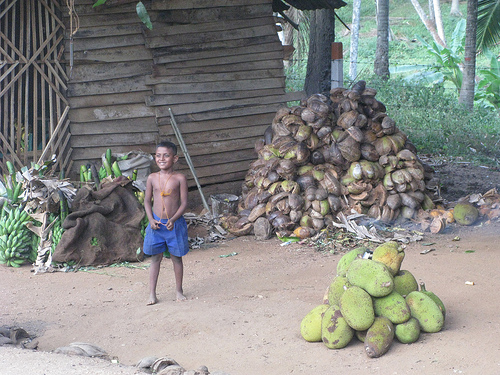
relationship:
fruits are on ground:
[344, 257, 396, 297] [1, 206, 499, 370]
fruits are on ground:
[368, 238, 405, 276] [1, 206, 499, 370]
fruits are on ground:
[397, 290, 449, 333] [1, 206, 499, 370]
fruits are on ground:
[336, 287, 378, 330] [1, 206, 499, 370]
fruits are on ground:
[361, 314, 396, 359] [1, 206, 499, 370]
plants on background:
[392, 60, 499, 150] [261, 49, 489, 92]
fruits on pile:
[338, 286, 375, 332] [300, 241, 444, 356]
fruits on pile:
[404, 291, 445, 334] [300, 241, 444, 356]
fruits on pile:
[371, 240, 404, 276] [300, 241, 444, 356]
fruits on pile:
[344, 257, 395, 297] [300, 241, 444, 356]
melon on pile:
[301, 305, 325, 340] [300, 241, 444, 356]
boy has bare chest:
[142, 141, 187, 306] [149, 171, 179, 208]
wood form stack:
[47, 2, 311, 203] [89, 23, 263, 146]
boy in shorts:
[132, 132, 208, 314] [145, 204, 197, 264]